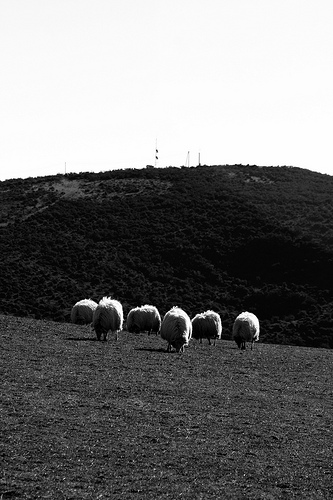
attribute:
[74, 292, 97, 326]
sheep — in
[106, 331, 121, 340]
feet — sheep's, back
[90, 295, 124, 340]
sheep — eating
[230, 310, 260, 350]
sheep — eating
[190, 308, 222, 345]
sheep — grazing, eating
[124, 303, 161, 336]
sheep — eating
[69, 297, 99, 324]
sheep — eating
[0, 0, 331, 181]
sky — cloudless, white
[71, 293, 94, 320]
sheep — in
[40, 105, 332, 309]
vegetation — dense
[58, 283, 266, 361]
sheep — white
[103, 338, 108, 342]
feet — sheep's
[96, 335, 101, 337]
feet — sheep's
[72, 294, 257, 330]
fur — long, sheep's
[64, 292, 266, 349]
group — sheep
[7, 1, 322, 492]
photo — black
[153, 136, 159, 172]
structure — metal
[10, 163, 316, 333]
formation — hilltop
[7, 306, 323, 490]
field — grass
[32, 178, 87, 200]
spot — dirt, bald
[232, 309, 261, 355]
sheep — grazing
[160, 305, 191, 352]
sheep — grazing, eating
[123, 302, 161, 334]
sheep — grazing